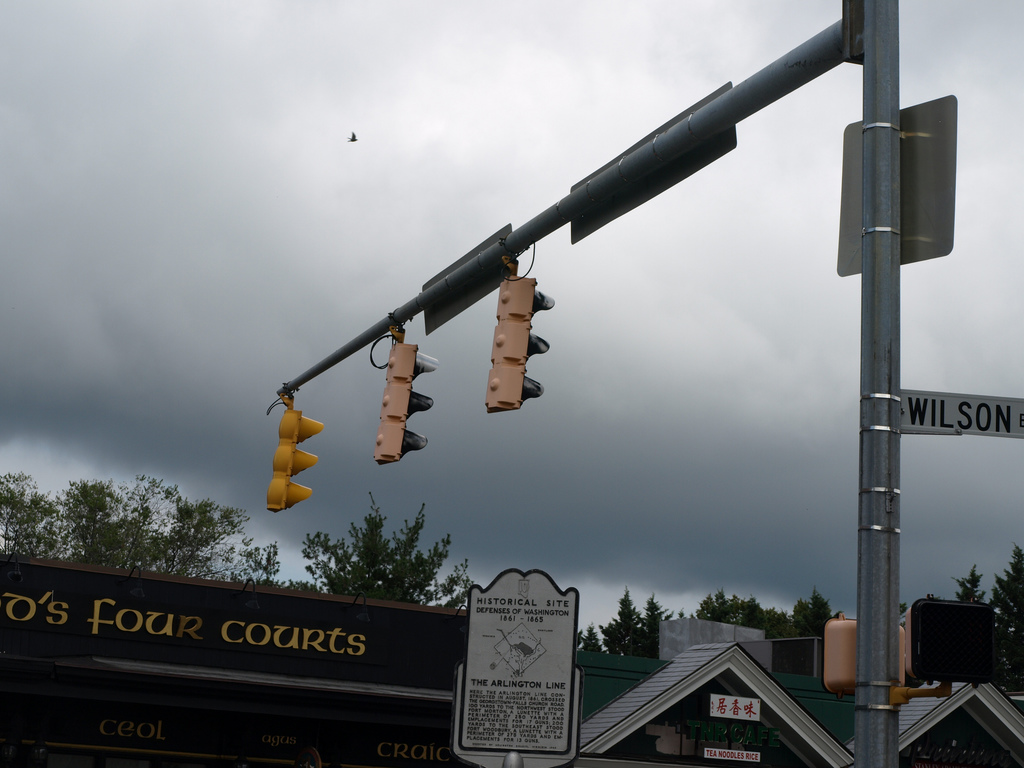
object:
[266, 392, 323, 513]
lights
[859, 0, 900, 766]
pole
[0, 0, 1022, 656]
sky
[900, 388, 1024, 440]
sign